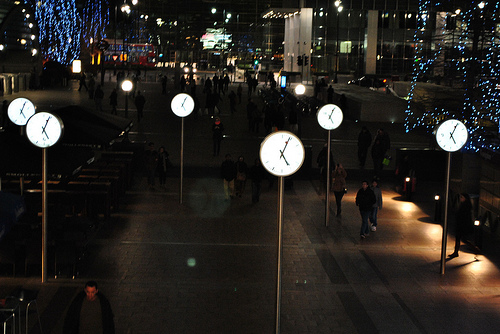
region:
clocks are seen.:
[8, 88, 479, 198]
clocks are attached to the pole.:
[5, 85, 467, 321]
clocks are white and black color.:
[255, 125, 306, 175]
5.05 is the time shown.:
[238, 125, 309, 185]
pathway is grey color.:
[200, 245, 260, 305]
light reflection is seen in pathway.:
[362, 157, 488, 308]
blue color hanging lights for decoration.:
[35, 1, 137, 52]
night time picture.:
[25, 16, 462, 303]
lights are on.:
[112, 7, 453, 83]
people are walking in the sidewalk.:
[120, 59, 370, 319]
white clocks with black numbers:
[9, 92, 69, 154]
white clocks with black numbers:
[244, 92, 354, 199]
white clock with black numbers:
[418, 115, 466, 160]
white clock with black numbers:
[154, 90, 205, 130]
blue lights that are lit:
[8, 2, 123, 61]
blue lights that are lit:
[402, 3, 497, 124]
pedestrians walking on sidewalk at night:
[330, 150, 425, 296]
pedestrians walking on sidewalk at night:
[20, 256, 137, 332]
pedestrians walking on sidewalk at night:
[183, 120, 254, 232]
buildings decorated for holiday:
[136, 8, 375, 90]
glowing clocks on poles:
[234, 98, 489, 281]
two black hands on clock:
[274, 132, 294, 176]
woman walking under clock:
[439, 182, 481, 271]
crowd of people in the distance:
[197, 62, 292, 125]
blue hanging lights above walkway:
[29, 7, 89, 69]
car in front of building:
[345, 71, 396, 91]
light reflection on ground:
[394, 192, 462, 264]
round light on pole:
[116, 76, 143, 98]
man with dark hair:
[70, 274, 115, 323]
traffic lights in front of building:
[292, 50, 314, 73]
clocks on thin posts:
[15, 45, 478, 308]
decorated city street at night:
[30, 16, 477, 311]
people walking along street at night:
[280, 90, 452, 277]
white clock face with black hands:
[245, 116, 310, 191]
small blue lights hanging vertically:
[31, 5, 101, 70]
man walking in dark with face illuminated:
[50, 266, 140, 321]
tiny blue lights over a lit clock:
[395, 25, 495, 160]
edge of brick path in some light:
[271, 205, 347, 325]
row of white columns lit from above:
[270, 10, 340, 85]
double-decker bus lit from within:
[108, 28, 173, 73]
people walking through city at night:
[19, 7, 469, 294]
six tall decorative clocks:
[14, 78, 471, 323]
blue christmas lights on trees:
[26, 0, 106, 74]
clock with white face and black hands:
[258, 124, 324, 189]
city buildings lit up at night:
[78, 8, 433, 76]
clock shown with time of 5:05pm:
[160, 86, 216, 138]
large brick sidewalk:
[167, 197, 236, 296]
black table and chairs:
[5, 214, 89, 277]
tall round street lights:
[105, 71, 147, 131]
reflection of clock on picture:
[171, 161, 239, 235]